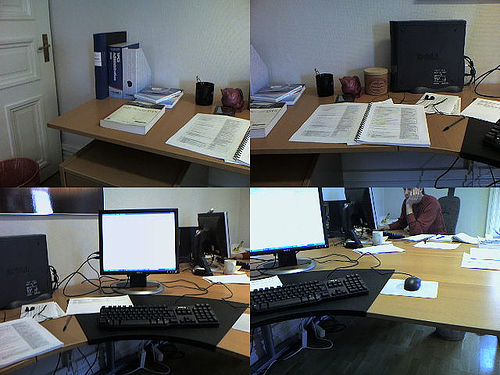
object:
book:
[287, 98, 435, 149]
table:
[250, 86, 500, 155]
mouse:
[403, 276, 422, 292]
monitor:
[98, 207, 178, 276]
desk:
[2, 247, 249, 373]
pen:
[61, 315, 74, 333]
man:
[379, 187, 447, 235]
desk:
[250, 232, 499, 333]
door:
[2, 0, 65, 181]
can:
[0, 156, 43, 189]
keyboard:
[97, 302, 220, 331]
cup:
[371, 229, 382, 243]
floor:
[253, 313, 499, 374]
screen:
[249, 188, 326, 253]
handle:
[38, 33, 51, 63]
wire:
[162, 278, 208, 298]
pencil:
[314, 68, 319, 74]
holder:
[313, 66, 336, 99]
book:
[99, 99, 167, 136]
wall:
[50, 0, 249, 31]